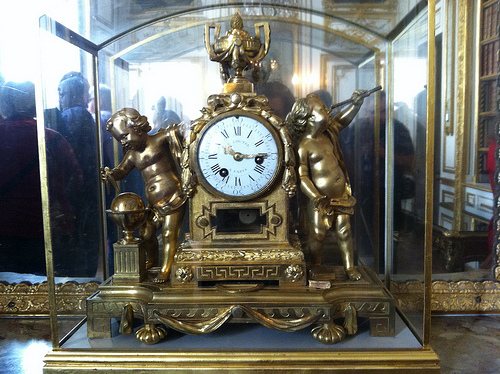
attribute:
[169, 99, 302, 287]
clock — golden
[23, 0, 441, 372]
case — glass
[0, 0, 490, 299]
mirror — big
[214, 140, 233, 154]
hand — short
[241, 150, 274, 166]
hand — long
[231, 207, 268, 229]
bell — clock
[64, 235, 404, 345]
stand — clock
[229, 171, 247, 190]
six — numeral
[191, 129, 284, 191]
face — white, clock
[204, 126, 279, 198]
numbers — clock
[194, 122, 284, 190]
numerals — roman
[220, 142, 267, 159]
hands — clock, bronze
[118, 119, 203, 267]
children — sculptures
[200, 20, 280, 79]
carving — top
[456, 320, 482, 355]
case — glass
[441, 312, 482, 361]
table — wood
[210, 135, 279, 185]
numerals — roman, black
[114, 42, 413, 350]
clock — bronze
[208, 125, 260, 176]
numerals — roman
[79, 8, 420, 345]
clock — bronze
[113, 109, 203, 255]
children — statues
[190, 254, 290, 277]
design — decorative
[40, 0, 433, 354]
case — glass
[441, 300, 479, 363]
table — brown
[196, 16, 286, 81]
statue — top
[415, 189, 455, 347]
frame — bronze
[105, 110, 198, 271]
cherub — golden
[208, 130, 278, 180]
face — black clock , round white  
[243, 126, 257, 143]
one —  clock , roman numeral 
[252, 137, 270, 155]
two — roman numeral , clock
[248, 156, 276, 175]
four — clock, roman numeral 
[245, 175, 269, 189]
five — roman numeral , clock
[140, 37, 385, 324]
clock — golden, cherubs design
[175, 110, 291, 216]
clock — golden top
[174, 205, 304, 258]
design — golden globe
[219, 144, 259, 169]
glass — golden clock 